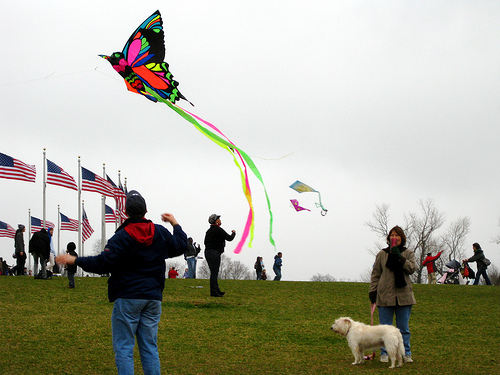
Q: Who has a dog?
A: Woman.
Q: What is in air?
A: Kite.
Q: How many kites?
A: Three.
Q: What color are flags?
A: Red white blue.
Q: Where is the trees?
A: Behind woman on right.